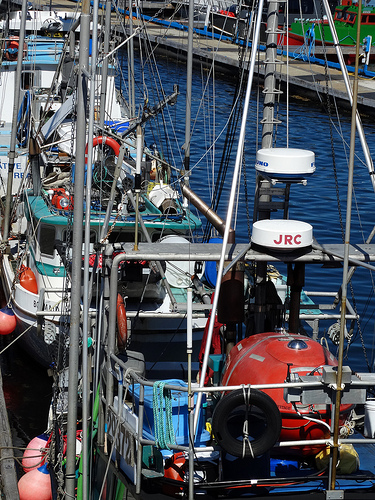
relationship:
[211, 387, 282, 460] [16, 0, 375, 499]
tire on back of boat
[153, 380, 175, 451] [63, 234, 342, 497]
rope to boat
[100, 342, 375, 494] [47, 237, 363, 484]
railing around outside of boat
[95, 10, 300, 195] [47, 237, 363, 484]
wires on top of boat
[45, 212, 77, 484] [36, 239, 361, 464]
chain tied to boat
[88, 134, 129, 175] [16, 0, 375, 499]
life wheel on boat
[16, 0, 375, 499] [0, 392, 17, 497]
boat parked at dock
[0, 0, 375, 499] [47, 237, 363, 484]
bouys hanging from boat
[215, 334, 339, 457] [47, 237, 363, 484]
engine on boat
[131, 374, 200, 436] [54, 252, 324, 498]
tub on boat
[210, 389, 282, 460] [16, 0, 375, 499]
tire hanging from side of boat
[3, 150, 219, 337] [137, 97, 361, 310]
boat in water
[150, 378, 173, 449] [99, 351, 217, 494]
rope wrapped around railing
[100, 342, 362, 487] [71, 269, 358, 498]
railing on boat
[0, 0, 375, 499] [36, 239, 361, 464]
bouys attached to boat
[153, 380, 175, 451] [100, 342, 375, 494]
rope on railing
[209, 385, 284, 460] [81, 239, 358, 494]
chord on boat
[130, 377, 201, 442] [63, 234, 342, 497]
container on boat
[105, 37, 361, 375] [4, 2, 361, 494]
water beside boats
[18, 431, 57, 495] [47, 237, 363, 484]
bouys by boat